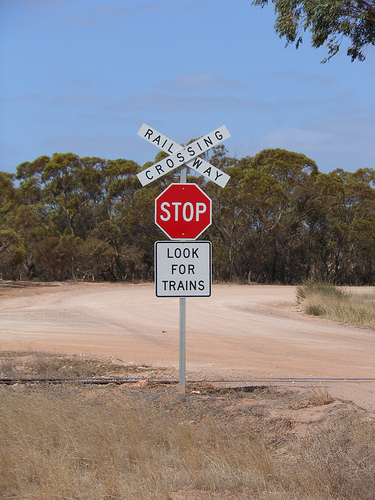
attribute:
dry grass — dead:
[27, 408, 182, 492]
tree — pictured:
[16, 151, 112, 235]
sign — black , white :
[162, 237, 207, 297]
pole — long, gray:
[155, 128, 199, 405]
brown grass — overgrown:
[1, 351, 373, 497]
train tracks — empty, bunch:
[0, 369, 374, 394]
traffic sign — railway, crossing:
[135, 120, 232, 192]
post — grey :
[174, 159, 187, 392]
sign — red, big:
[140, 183, 217, 244]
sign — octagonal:
[148, 182, 212, 243]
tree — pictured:
[14, 189, 90, 251]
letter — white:
[159, 201, 171, 224]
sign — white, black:
[158, 244, 208, 297]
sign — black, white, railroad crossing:
[134, 122, 234, 186]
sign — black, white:
[151, 182, 214, 238]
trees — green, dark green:
[1, 147, 374, 293]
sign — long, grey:
[152, 230, 223, 308]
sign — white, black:
[150, 244, 216, 301]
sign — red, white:
[155, 184, 210, 237]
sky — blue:
[1, 2, 374, 210]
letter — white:
[180, 199, 194, 226]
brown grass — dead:
[110, 416, 255, 487]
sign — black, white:
[152, 238, 213, 297]